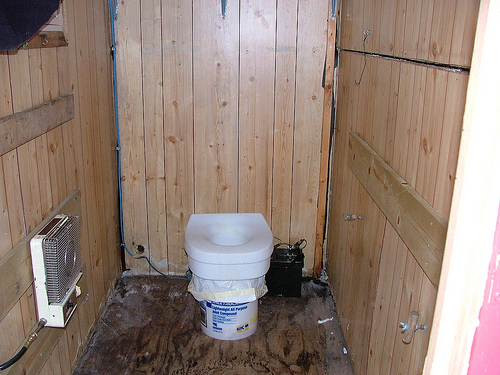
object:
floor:
[66, 272, 356, 374]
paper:
[315, 316, 334, 325]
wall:
[111, 0, 338, 288]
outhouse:
[0, 0, 500, 375]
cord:
[106, 0, 124, 248]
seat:
[182, 213, 278, 265]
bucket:
[198, 297, 259, 340]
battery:
[264, 235, 308, 298]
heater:
[30, 212, 87, 329]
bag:
[187, 275, 267, 303]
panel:
[272, 0, 297, 248]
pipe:
[335, 47, 471, 76]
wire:
[318, 0, 339, 276]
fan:
[64, 239, 77, 275]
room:
[0, 0, 499, 375]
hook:
[353, 28, 371, 86]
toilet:
[183, 213, 275, 343]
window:
[0, 0, 63, 52]